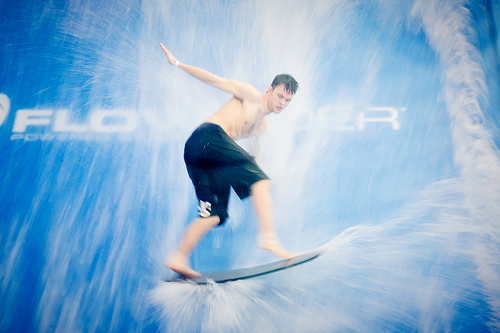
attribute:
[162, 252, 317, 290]
surfboard — small, blue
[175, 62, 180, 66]
wristband — white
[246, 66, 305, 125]
hair — short brown, wet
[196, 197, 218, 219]
logo — white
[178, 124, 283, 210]
shorts — blue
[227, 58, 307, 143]
boy — white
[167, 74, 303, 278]
boy — shirtless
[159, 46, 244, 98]
arm — extended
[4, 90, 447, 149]
advertisement — white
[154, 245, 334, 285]
surfboard — small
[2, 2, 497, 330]
water — white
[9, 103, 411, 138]
lettering — white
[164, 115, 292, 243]
trunks — blue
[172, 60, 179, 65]
bracelet — white